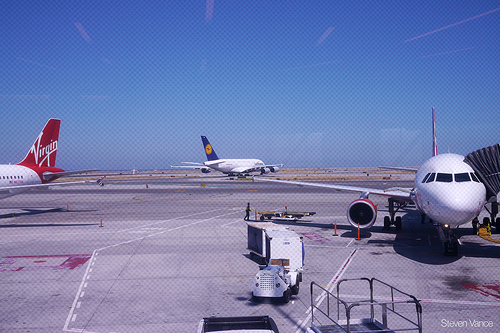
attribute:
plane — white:
[185, 134, 286, 180]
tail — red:
[14, 114, 66, 183]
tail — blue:
[200, 133, 216, 142]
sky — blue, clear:
[219, 46, 255, 93]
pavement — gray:
[120, 218, 174, 277]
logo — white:
[31, 135, 62, 153]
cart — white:
[253, 227, 312, 291]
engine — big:
[349, 194, 373, 229]